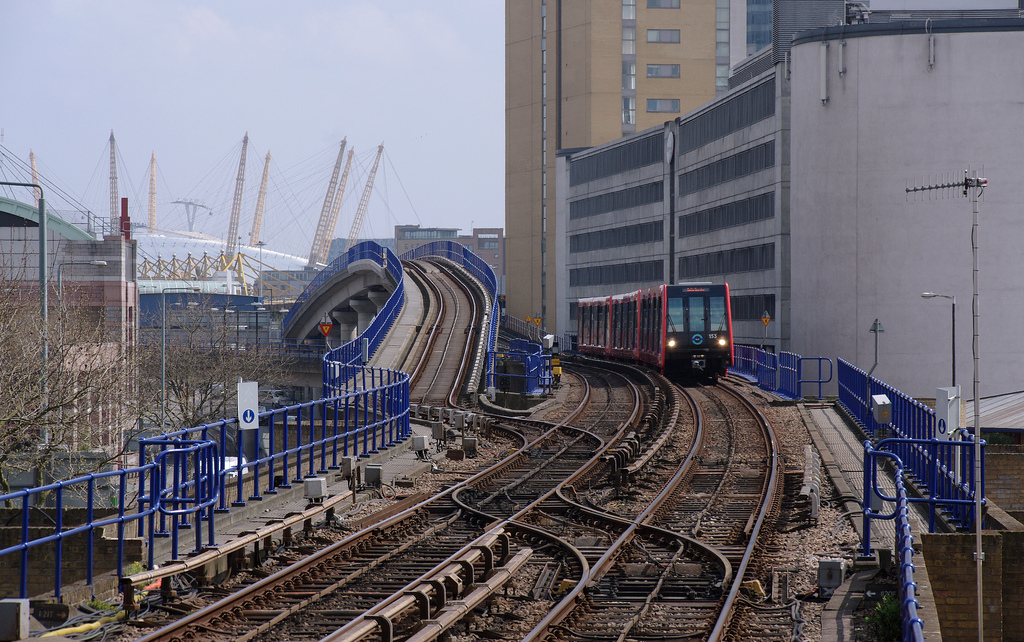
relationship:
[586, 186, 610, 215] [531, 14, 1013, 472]
window on building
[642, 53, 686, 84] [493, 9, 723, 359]
window on building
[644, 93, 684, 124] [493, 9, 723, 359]
window on building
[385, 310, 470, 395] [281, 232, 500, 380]
rail on bridge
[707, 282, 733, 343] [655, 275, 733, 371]
window in front of train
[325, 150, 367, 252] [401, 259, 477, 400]
crane behind rail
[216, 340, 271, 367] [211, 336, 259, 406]
leaves are attached to tree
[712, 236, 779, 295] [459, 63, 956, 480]
window on building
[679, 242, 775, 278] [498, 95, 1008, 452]
window on building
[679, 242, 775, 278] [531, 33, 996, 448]
window on building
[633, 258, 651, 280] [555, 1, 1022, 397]
window on building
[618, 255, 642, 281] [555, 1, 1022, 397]
window on building